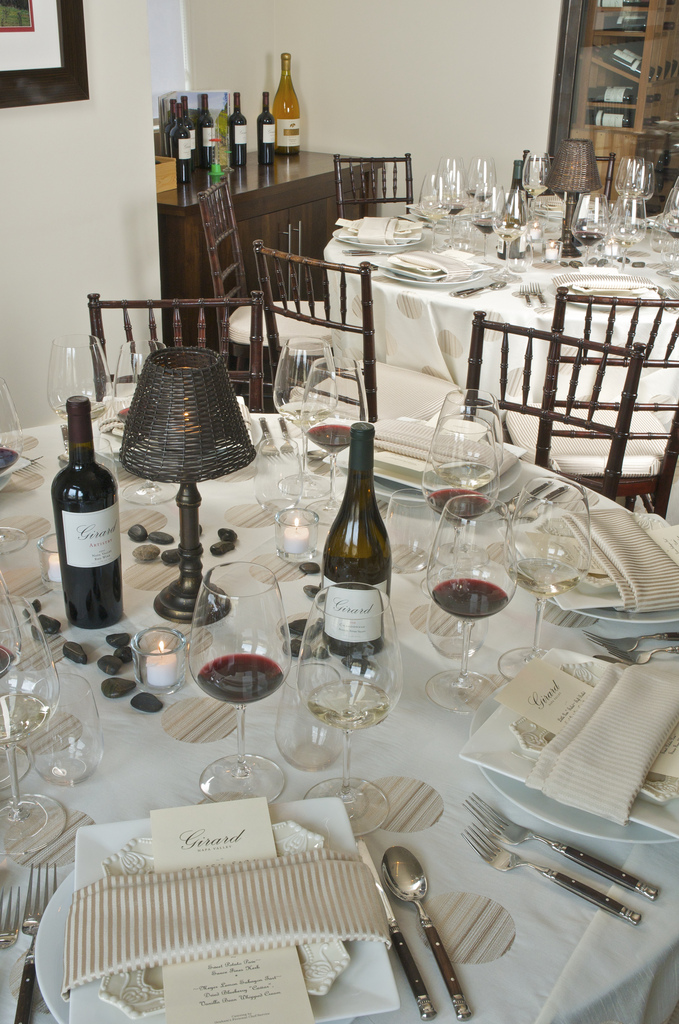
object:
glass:
[496, 474, 593, 683]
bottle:
[50, 391, 124, 634]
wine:
[50, 394, 125, 631]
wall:
[0, 0, 561, 428]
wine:
[507, 555, 580, 599]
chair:
[251, 234, 379, 427]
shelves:
[591, 2, 653, 34]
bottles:
[590, 41, 656, 85]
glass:
[580, 0, 679, 130]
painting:
[0, 0, 94, 117]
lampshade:
[119, 342, 258, 486]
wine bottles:
[256, 87, 278, 172]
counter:
[155, 145, 382, 369]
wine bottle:
[318, 417, 393, 661]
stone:
[131, 543, 161, 561]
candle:
[144, 636, 178, 689]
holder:
[129, 623, 187, 700]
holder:
[274, 506, 320, 565]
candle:
[282, 515, 310, 555]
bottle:
[271, 47, 301, 155]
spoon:
[380, 842, 475, 1022]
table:
[0, 402, 679, 1021]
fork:
[460, 818, 644, 927]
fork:
[462, 787, 662, 902]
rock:
[128, 690, 163, 713]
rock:
[99, 675, 137, 699]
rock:
[62, 639, 89, 666]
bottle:
[256, 88, 275, 167]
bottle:
[227, 89, 249, 170]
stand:
[152, 50, 368, 357]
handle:
[419, 913, 475, 1021]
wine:
[196, 652, 286, 705]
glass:
[188, 559, 292, 806]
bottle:
[195, 89, 217, 172]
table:
[156, 148, 382, 355]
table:
[322, 200, 679, 499]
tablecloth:
[323, 212, 678, 417]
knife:
[355, 838, 437, 1017]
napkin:
[60, 847, 393, 999]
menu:
[493, 653, 679, 787]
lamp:
[117, 341, 258, 629]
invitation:
[147, 788, 322, 1024]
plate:
[30, 802, 405, 1023]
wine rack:
[545, 0, 678, 204]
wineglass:
[424, 490, 520, 715]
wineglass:
[295, 577, 405, 841]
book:
[157, 90, 176, 158]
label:
[60, 498, 136, 570]